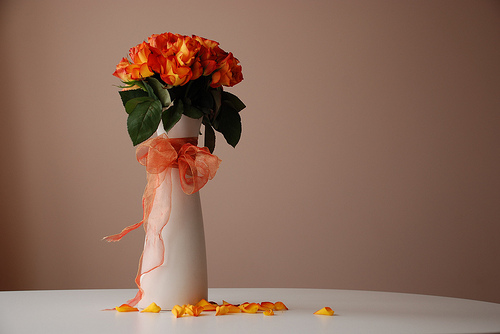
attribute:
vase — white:
[133, 108, 209, 314]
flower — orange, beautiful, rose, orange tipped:
[164, 61, 192, 86]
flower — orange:
[223, 55, 242, 85]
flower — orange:
[114, 57, 134, 80]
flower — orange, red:
[154, 35, 182, 52]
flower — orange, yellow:
[183, 35, 200, 60]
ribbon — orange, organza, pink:
[104, 136, 222, 310]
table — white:
[0, 289, 500, 333]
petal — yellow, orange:
[312, 306, 334, 313]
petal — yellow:
[143, 304, 160, 314]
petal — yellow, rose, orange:
[116, 305, 140, 312]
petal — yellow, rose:
[171, 304, 184, 318]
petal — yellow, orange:
[216, 306, 230, 314]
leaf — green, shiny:
[127, 99, 161, 144]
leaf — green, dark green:
[217, 105, 241, 149]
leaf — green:
[162, 98, 185, 135]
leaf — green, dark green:
[195, 86, 215, 110]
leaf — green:
[121, 91, 149, 105]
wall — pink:
[0, 1, 498, 302]